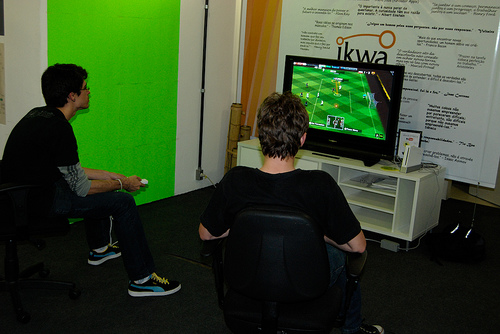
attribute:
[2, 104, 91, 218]
shirt — black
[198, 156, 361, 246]
shirt — black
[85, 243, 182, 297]
shoes — blue, black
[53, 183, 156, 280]
jeans — dark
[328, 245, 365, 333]
jeans — dark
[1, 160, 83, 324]
chair — black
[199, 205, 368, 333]
chair — black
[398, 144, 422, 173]
game — white, wii, soccer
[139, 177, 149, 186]
controller — white, wii remote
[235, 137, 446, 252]
tv stand — white, furniture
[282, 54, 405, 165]
television — black, flat screen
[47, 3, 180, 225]
wall — green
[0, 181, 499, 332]
floor — gray, carpeted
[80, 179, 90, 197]
elbow — bent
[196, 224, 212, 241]
elbow — bent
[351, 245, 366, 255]
elbow — bent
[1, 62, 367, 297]
men — gaming